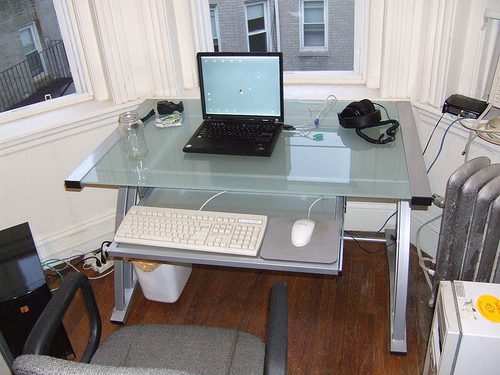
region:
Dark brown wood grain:
[355, 258, 382, 290]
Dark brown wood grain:
[353, 299, 373, 316]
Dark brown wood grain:
[345, 337, 375, 359]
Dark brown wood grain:
[304, 336, 326, 358]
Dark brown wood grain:
[310, 299, 336, 322]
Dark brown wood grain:
[318, 279, 352, 299]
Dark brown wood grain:
[215, 297, 258, 329]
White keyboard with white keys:
[113, 199, 268, 264]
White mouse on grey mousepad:
[277, 206, 315, 267]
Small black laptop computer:
[171, 36, 299, 171]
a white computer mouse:
[290, 216, 316, 247]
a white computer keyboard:
[110, 200, 270, 255]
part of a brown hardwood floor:
[45, 235, 437, 370]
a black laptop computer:
[180, 45, 290, 157]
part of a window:
[200, 1, 357, 76]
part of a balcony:
[0, 40, 72, 107]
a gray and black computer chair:
[0, 276, 296, 373]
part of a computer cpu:
[423, 275, 498, 372]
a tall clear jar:
[117, 110, 152, 161]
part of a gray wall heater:
[432, 153, 498, 283]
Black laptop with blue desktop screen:
[179, 49, 288, 159]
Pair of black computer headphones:
[337, 98, 400, 148]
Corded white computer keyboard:
[114, 192, 268, 256]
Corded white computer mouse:
[287, 195, 326, 247]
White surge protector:
[87, 240, 114, 274]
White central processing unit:
[417, 280, 499, 373]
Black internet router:
[442, 93, 487, 122]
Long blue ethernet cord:
[342, 113, 465, 240]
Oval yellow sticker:
[476, 293, 498, 325]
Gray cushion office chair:
[9, 270, 289, 373]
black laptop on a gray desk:
[182, 49, 284, 156]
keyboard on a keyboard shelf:
[114, 207, 269, 254]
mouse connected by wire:
[289, 217, 316, 247]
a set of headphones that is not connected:
[337, 98, 400, 143]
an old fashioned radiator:
[429, 157, 499, 311]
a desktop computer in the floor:
[420, 279, 498, 373]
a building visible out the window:
[205, 2, 352, 72]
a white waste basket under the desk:
[131, 257, 191, 304]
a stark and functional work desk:
[65, 101, 432, 348]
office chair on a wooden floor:
[12, 277, 291, 374]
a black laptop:
[181, 51, 281, 157]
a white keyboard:
[111, 205, 266, 255]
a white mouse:
[290, 215, 315, 245]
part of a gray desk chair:
[17, 276, 283, 367]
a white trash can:
[130, 260, 190, 301]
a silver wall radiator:
[430, 152, 496, 302]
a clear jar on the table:
[115, 107, 147, 157]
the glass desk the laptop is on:
[65, 95, 430, 195]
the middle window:
[207, 0, 352, 70]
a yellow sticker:
[475, 292, 497, 323]